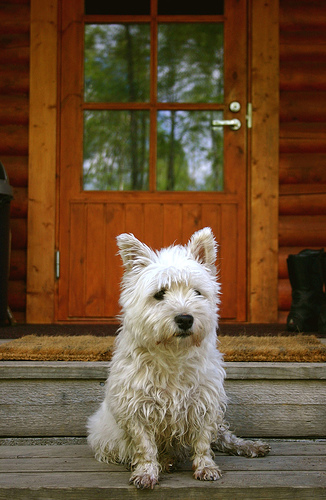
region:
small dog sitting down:
[79, 218, 262, 499]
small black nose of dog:
[163, 314, 198, 332]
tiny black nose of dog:
[170, 315, 193, 329]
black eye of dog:
[153, 286, 170, 302]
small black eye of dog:
[190, 290, 203, 298]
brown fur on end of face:
[150, 329, 208, 356]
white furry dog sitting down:
[87, 223, 267, 482]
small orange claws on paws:
[139, 477, 156, 490]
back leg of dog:
[219, 429, 279, 462]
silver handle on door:
[211, 116, 246, 132]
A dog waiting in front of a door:
[73, 223, 275, 492]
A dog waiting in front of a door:
[80, 221, 274, 490]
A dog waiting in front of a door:
[76, 220, 274, 498]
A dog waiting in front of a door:
[78, 223, 268, 490]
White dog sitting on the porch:
[86, 226, 269, 488]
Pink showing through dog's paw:
[128, 472, 159, 487]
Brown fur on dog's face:
[155, 329, 203, 351]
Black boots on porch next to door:
[284, 248, 324, 336]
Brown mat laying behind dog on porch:
[1, 333, 325, 363]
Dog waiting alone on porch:
[86, 226, 271, 489]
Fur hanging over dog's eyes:
[153, 267, 189, 288]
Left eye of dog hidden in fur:
[190, 285, 205, 299]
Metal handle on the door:
[211, 118, 240, 129]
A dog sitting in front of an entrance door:
[70, 222, 280, 491]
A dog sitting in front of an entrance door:
[81, 222, 275, 492]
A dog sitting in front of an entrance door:
[76, 221, 277, 495]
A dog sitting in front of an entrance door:
[78, 221, 271, 491]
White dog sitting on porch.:
[88, 225, 270, 485]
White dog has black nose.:
[175, 315, 193, 328]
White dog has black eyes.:
[152, 289, 201, 297]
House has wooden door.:
[54, 0, 250, 322]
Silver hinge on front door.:
[54, 250, 58, 276]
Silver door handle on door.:
[210, 119, 240, 128]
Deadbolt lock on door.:
[228, 101, 239, 109]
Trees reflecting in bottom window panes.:
[81, 23, 224, 189]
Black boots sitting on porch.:
[284, 248, 324, 337]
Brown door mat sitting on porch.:
[0, 334, 324, 361]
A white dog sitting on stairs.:
[86, 226, 269, 488]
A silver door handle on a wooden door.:
[213, 119, 240, 129]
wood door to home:
[29, 8, 270, 331]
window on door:
[151, 109, 220, 186]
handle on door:
[201, 107, 236, 129]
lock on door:
[225, 95, 239, 109]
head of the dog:
[103, 220, 222, 341]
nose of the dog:
[169, 311, 187, 326]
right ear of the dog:
[106, 227, 147, 266]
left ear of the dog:
[177, 225, 209, 267]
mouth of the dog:
[167, 328, 197, 337]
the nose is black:
[170, 310, 198, 333]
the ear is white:
[108, 225, 153, 262]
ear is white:
[189, 228, 221, 271]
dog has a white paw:
[118, 449, 162, 494]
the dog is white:
[78, 232, 274, 490]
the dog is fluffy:
[84, 227, 279, 490]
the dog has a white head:
[109, 225, 221, 362]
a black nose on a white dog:
[167, 311, 201, 346]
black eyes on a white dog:
[143, 273, 211, 309]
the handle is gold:
[205, 110, 246, 137]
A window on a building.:
[158, 104, 229, 209]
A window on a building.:
[79, 17, 155, 103]